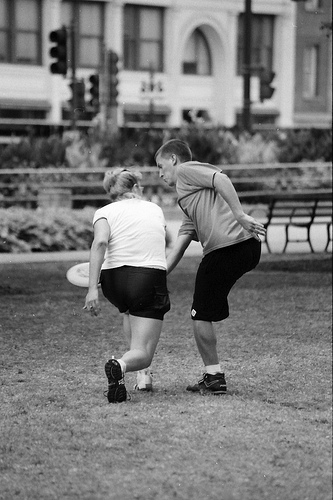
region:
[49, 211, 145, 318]
frisbee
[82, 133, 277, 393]
Man and woman play frisbee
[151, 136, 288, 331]
Man wears dark shorts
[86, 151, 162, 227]
Blonde woman has hair up in ponytail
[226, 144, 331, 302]
Bench by play field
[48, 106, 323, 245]
Many bushes along roadway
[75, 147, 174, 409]
Woman wears short dark shorts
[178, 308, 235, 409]
Man wears Nike shoes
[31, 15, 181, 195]
stoplights behind play field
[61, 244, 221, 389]
Woman wears ring on finger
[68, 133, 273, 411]
People playing frisbee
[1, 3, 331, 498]
Picture is white and black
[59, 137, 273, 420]
Persons are disputing a frisbee.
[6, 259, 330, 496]
Field is cover with grass.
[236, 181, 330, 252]
Bench on side of field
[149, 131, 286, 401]
Man wears a dark t-shirt.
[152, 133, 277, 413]
Man wears black shorts.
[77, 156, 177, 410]
Woman has right knee bend.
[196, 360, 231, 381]
White socks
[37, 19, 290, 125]
Traffic lights on street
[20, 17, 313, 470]
Black and white picture.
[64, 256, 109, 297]
One Frisbee is flying in air.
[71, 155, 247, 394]
One man and woman are playing Frisbee.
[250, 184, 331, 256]
One bench is found in the sidewalk.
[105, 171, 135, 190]
Woman hair is blonde.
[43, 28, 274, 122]
Traffic lights are attached to the poles.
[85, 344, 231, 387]
Socks are white color.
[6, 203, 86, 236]
Bushes are found in the sides of the pathway.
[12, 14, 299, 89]
Buildings are found behind the bushes.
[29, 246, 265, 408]
People are playing in grass.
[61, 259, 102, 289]
A white frisbee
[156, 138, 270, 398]
A man playing frisbee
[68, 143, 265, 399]
Two people playing frisbee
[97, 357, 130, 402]
The sole of a sneaker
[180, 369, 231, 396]
A nike sneaker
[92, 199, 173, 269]
A white t shirt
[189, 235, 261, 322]
A pair of shorts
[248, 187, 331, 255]
A bench on a sidewalk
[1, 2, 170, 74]
Windows on a building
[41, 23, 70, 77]
A traffic signal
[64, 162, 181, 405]
a woman playing frisbee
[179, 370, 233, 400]
a black nike shoe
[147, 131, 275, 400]
a man reaching for something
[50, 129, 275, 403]
a man and woman playing with a flying disc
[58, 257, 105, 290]
a white flying disc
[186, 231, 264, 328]
a pair of black shorts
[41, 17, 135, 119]
out of focus street lights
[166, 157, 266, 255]
a grey striped shirt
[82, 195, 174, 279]
a plain white shirt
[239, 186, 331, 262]
a metal park bench